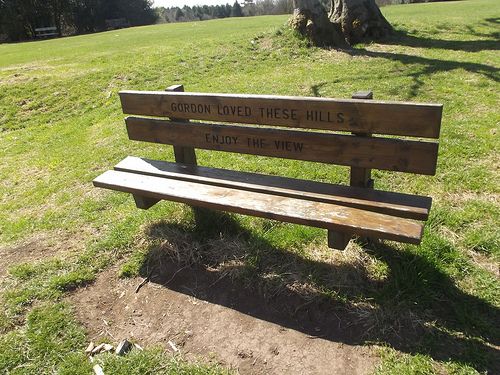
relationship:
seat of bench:
[90, 151, 432, 248] [90, 82, 443, 249]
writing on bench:
[167, 96, 347, 156] [90, 82, 443, 249]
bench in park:
[92, 83, 441, 251] [17, 26, 491, 351]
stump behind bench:
[292, 1, 403, 48] [90, 82, 443, 249]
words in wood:
[160, 102, 352, 125] [272, 95, 344, 106]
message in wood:
[170, 101, 345, 155] [95, 79, 469, 268]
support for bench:
[302, 79, 394, 286] [76, 54, 453, 304]